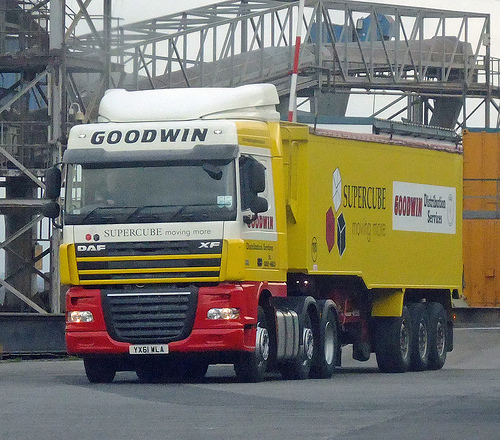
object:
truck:
[49, 83, 466, 379]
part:
[196, 295, 253, 347]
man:
[91, 170, 139, 208]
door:
[234, 136, 277, 269]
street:
[0, 355, 500, 436]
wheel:
[376, 305, 414, 372]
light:
[219, 308, 238, 320]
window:
[239, 159, 270, 210]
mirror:
[250, 197, 268, 213]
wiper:
[141, 203, 230, 207]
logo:
[323, 168, 350, 256]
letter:
[89, 127, 209, 146]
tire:
[313, 298, 341, 377]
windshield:
[63, 160, 228, 221]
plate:
[129, 344, 168, 354]